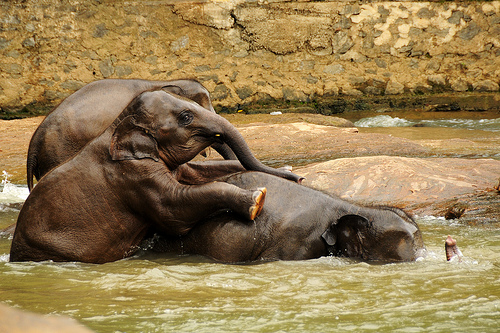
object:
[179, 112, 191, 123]
eye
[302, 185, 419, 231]
hair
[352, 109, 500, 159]
water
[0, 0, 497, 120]
rock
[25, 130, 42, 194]
tail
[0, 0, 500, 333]
photo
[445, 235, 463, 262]
elephant nose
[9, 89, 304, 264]
elephant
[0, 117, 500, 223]
flat rocks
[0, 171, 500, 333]
water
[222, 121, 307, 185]
elephant trunk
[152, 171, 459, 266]
elephant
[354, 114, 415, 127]
wave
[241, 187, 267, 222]
feet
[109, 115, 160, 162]
ear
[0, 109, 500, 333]
river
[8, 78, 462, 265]
elephants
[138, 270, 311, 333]
waves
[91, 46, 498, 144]
wall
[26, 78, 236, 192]
elephant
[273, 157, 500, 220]
rock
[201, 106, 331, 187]
trunk